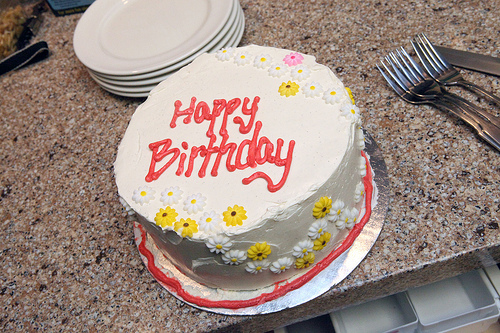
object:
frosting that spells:
[145, 85, 304, 199]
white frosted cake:
[108, 46, 385, 316]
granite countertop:
[1, 0, 497, 331]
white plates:
[71, 1, 260, 98]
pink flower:
[274, 48, 310, 71]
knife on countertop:
[415, 36, 499, 76]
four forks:
[361, 31, 498, 144]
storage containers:
[333, 262, 499, 332]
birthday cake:
[108, 47, 382, 297]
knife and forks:
[382, 31, 498, 147]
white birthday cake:
[113, 40, 377, 300]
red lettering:
[141, 91, 299, 194]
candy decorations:
[113, 44, 375, 321]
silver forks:
[375, 29, 499, 156]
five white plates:
[70, 0, 259, 104]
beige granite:
[0, 1, 500, 331]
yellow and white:
[114, 40, 378, 305]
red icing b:
[142, 139, 185, 183]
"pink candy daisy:
[109, 40, 381, 286]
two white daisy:
[304, 80, 344, 108]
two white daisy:
[304, 76, 345, 104]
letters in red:
[145, 80, 297, 195]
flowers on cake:
[114, 26, 374, 300]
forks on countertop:
[358, 30, 498, 161]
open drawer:
[327, 257, 498, 330]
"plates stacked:
[73, 2, 248, 100]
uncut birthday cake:
[113, 48, 381, 306]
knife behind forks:
[405, 36, 498, 78]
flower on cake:
[274, 46, 308, 68]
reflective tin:
[130, 125, 401, 308]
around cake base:
[135, 151, 386, 313]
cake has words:
[146, 95, 297, 191]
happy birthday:
[126, 90, 302, 196]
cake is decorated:
[110, 42, 379, 293]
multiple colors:
[114, 45, 380, 313]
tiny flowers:
[118, 42, 371, 280]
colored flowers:
[120, 44, 378, 274]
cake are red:
[138, 95, 299, 193]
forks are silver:
[368, 30, 499, 147]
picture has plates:
[73, 0, 245, 100]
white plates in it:
[67, 0, 247, 99]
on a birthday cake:
[141, 48, 306, 191]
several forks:
[375, 38, 498, 152]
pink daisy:
[284, 45, 311, 68]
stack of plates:
[71, 1, 271, 100]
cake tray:
[112, 42, 392, 316]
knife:
[412, 36, 496, 83]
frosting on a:
[115, 45, 380, 302]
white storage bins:
[327, 262, 499, 332]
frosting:
[130, 79, 291, 201]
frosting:
[305, 123, 338, 213]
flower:
[150, 189, 217, 240]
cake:
[104, 38, 378, 308]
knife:
[408, 32, 498, 89]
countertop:
[6, 112, 105, 310]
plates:
[65, 52, 254, 102]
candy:
[117, 185, 246, 247]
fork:
[371, 57, 498, 162]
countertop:
[2, 107, 497, 333]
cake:
[94, 52, 395, 311]